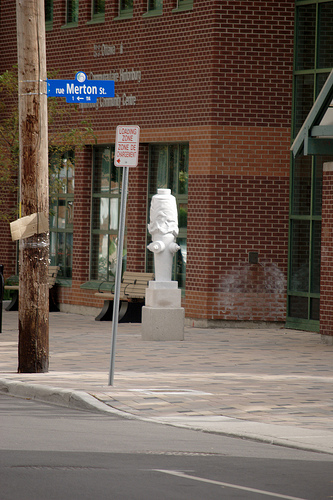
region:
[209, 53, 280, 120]
a red brick wall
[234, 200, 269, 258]
a red brick wall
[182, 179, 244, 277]
a red brick wall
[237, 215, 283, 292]
a red brick wall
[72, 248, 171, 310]
the bench is empty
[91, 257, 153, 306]
the bench is empty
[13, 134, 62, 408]
the pole is brown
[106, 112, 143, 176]
warning traffic sign posted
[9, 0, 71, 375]
tall bare tree trunk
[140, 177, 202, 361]
statue in the middle of street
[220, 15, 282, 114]
brick wall of building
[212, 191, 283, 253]
brick wall of building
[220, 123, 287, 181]
brick wall of building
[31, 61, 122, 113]
street sign on post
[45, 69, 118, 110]
blue sign with white letters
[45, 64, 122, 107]
name of street on sign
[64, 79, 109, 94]
white letters in sign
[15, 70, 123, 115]
This is a street sign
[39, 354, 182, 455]
this is a sidewalk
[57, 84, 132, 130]
The sign is blue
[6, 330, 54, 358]
This is a telephone pole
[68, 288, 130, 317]
This is a bench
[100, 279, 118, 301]
The bench is wooden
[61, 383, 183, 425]
The ground is cobblestone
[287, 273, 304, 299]
This is a door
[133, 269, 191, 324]
This is a hydrant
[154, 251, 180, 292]
This is grey marble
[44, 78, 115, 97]
Blue sign that says Merton St.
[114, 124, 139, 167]
Red and white loading zone sign.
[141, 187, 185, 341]
White concrete statue with a flat top.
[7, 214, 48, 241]
Cardboard on a brown utility pole.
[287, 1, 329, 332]
Many large green windows going from right top to bottom.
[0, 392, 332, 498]
Grey road with white lines in it.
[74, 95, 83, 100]
White arrow pointing left under Merton St.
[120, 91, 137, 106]
The word Centre on the red brick building.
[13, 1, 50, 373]
A dark and light brown utility pole.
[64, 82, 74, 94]
The M in Merton.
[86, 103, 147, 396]
A loading zone sign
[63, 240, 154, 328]
A wooden bench on a sidewalk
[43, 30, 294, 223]
A community center building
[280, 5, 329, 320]
Tall glass windows in a brick building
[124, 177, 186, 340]
Tall white sculpture on concrete blocks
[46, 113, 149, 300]
Front windows to brick building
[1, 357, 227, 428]
Curb and street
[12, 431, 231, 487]
Manholes on the street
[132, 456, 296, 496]
White dashed line on the street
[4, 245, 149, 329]
Two wooden benches on the sidewalk